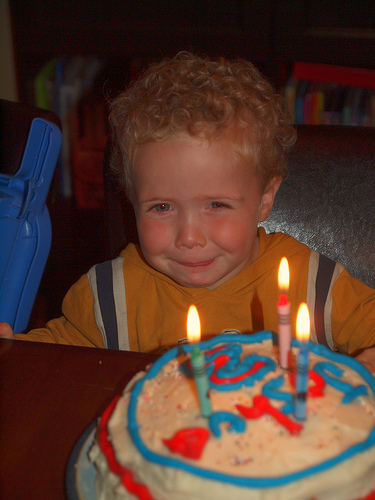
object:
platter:
[61, 415, 98, 499]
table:
[2, 335, 164, 498]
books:
[286, 83, 296, 130]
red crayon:
[272, 292, 295, 369]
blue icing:
[141, 451, 170, 468]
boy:
[0, 52, 375, 373]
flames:
[185, 305, 204, 348]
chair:
[286, 119, 373, 166]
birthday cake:
[61, 330, 374, 498]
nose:
[173, 215, 207, 252]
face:
[131, 137, 253, 287]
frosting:
[88, 324, 373, 497]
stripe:
[86, 259, 128, 344]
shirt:
[14, 231, 373, 352]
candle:
[274, 252, 294, 369]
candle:
[293, 301, 311, 423]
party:
[2, 4, 351, 495]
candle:
[183, 302, 212, 415]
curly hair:
[104, 46, 295, 208]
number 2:
[183, 344, 276, 389]